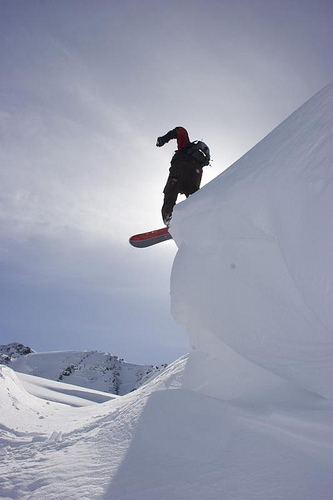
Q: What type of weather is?
A: It is cloudy.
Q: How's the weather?
A: It is cloudy.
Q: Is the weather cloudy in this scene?
A: Yes, it is cloudy.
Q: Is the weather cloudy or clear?
A: It is cloudy.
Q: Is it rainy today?
A: No, it is cloudy.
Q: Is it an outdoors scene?
A: Yes, it is outdoors.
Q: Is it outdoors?
A: Yes, it is outdoors.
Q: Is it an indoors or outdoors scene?
A: It is outdoors.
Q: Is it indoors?
A: No, it is outdoors.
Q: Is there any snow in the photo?
A: Yes, there is snow.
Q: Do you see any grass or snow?
A: Yes, there is snow.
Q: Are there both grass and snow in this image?
A: No, there is snow but no grass.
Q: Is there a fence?
A: No, there are no fences.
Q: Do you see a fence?
A: No, there are no fences.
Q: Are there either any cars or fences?
A: No, there are no fences or cars.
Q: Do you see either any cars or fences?
A: No, there are no fences or cars.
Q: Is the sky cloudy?
A: Yes, the sky is cloudy.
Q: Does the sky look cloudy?
A: Yes, the sky is cloudy.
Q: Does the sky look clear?
A: No, the sky is cloudy.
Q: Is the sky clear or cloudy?
A: The sky is cloudy.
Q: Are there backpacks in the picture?
A: Yes, there is a backpack.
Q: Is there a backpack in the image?
A: Yes, there is a backpack.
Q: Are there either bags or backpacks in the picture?
A: Yes, there is a backpack.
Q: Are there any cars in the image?
A: No, there are no cars.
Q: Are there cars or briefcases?
A: No, there are no cars or briefcases.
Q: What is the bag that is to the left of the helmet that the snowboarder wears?
A: The bag is a backpack.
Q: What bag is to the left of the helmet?
A: The bag is a backpack.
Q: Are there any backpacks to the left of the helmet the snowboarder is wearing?
A: Yes, there is a backpack to the left of the helmet.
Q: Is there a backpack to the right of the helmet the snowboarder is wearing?
A: No, the backpack is to the left of the helmet.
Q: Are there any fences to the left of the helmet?
A: No, there is a backpack to the left of the helmet.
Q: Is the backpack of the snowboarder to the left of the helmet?
A: Yes, the backpack is to the left of the helmet.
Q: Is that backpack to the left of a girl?
A: No, the backpack is to the left of the helmet.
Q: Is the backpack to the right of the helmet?
A: No, the backpack is to the left of the helmet.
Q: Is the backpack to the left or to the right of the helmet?
A: The backpack is to the left of the helmet.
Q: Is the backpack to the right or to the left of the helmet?
A: The backpack is to the left of the helmet.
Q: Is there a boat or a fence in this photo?
A: No, there are no fences or boats.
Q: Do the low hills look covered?
A: Yes, the hills are covered.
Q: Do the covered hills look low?
A: Yes, the hills are low.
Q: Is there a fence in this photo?
A: No, there are no fences.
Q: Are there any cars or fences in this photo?
A: No, there are no fences or cars.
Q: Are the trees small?
A: Yes, the trees are small.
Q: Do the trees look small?
A: Yes, the trees are small.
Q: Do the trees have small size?
A: Yes, the trees are small.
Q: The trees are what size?
A: The trees are small.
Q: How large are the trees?
A: The trees are small.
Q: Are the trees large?
A: No, the trees are small.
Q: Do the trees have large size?
A: No, the trees are small.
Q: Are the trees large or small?
A: The trees are small.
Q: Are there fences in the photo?
A: No, there are no fences.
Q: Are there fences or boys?
A: No, there are no fences or boys.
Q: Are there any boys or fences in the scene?
A: No, there are no fences or boys.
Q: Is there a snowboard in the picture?
A: Yes, there is a snowboard.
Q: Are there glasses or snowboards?
A: Yes, there is a snowboard.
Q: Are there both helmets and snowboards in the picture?
A: Yes, there are both a snowboard and a helmet.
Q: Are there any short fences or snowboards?
A: Yes, there is a short snowboard.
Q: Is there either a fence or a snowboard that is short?
A: Yes, the snowboard is short.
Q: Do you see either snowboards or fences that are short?
A: Yes, the snowboard is short.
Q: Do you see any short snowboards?
A: Yes, there is a short snowboard.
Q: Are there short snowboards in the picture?
A: Yes, there is a short snowboard.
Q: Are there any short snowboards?
A: Yes, there is a short snowboard.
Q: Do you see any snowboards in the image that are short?
A: Yes, there is a snowboard that is short.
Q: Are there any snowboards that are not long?
A: Yes, there is a short snowboard.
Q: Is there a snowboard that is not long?
A: Yes, there is a short snowboard.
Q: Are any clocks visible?
A: No, there are no clocks.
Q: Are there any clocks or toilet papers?
A: No, there are no clocks or toilet papers.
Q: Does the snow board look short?
A: Yes, the snow board is short.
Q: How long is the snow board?
A: The snow board is short.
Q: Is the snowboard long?
A: No, the snowboard is short.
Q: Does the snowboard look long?
A: No, the snowboard is short.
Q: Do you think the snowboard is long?
A: No, the snowboard is short.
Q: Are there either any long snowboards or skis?
A: No, there is a snowboard but it is short.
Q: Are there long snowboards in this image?
A: No, there is a snowboard but it is short.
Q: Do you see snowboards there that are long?
A: No, there is a snowboard but it is short.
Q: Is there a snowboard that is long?
A: No, there is a snowboard but it is short.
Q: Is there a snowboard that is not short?
A: No, there is a snowboard but it is short.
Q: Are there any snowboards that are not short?
A: No, there is a snowboard but it is short.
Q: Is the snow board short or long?
A: The snow board is short.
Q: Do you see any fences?
A: No, there are no fences.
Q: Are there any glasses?
A: No, there are no glasses.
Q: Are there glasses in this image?
A: No, there are no glasses.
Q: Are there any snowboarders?
A: Yes, there is a snowboarder.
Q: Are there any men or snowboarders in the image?
A: Yes, there is a snowboarder.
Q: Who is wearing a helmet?
A: The snowboarder is wearing a helmet.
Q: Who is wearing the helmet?
A: The snowboarder is wearing a helmet.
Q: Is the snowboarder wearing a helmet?
A: Yes, the snowboarder is wearing a helmet.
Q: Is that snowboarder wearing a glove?
A: No, the snowboarder is wearing a helmet.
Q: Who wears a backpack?
A: The snowboarder wears a backpack.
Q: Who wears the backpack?
A: The snowboarder wears a backpack.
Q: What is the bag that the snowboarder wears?
A: The bag is a backpack.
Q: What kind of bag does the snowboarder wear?
A: The snowboarder wears a backpack.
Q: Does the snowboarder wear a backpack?
A: Yes, the snowboarder wears a backpack.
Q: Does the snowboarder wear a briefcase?
A: No, the snowboarder wears a backpack.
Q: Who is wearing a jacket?
A: The snowboarder is wearing a jacket.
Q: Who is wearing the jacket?
A: The snowboarder is wearing a jacket.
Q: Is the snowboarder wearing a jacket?
A: Yes, the snowboarder is wearing a jacket.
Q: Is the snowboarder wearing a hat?
A: No, the snowboarder is wearing a jacket.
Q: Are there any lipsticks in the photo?
A: No, there are no lipsticks.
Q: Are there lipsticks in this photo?
A: No, there are no lipsticks.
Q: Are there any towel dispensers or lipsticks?
A: No, there are no lipsticks or towel dispensers.